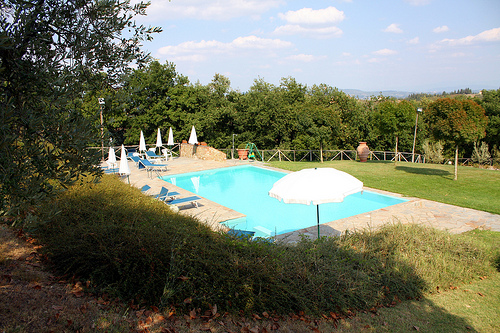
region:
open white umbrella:
[289, 166, 349, 198]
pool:
[190, 161, 255, 203]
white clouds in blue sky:
[176, 0, 210, 32]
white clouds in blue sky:
[175, 29, 227, 69]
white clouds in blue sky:
[240, 19, 317, 57]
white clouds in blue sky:
[246, 21, 330, 88]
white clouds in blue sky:
[306, 6, 361, 38]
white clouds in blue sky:
[309, 38, 359, 69]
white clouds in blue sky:
[363, 25, 428, 63]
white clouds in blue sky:
[363, 46, 421, 87]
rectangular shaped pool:
[164, 149, 401, 232]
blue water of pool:
[160, 161, 395, 242]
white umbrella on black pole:
[274, 164, 366, 242]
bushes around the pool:
[23, 174, 492, 319]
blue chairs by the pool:
[107, 145, 258, 242]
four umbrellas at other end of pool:
[139, 119, 197, 156]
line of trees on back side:
[75, 60, 495, 164]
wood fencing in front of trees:
[93, 137, 480, 168]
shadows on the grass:
[319, 236, 475, 331]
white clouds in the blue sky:
[148, 10, 494, 101]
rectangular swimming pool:
[163, 156, 415, 242]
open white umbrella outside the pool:
[266, 160, 369, 250]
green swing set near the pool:
[238, 141, 263, 166]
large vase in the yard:
[354, 139, 374, 165]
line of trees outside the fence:
[98, 61, 499, 166]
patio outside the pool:
[90, 149, 499, 279]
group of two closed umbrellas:
[105, 138, 130, 188]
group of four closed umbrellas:
[131, 109, 198, 158]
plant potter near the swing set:
[233, 145, 248, 160]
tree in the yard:
[426, 91, 493, 185]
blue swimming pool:
[219, 166, 269, 203]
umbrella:
[277, 162, 345, 212]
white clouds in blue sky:
[177, 6, 237, 44]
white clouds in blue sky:
[219, 5, 291, 55]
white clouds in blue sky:
[353, 28, 403, 68]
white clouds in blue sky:
[390, 15, 445, 49]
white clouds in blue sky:
[385, 32, 443, 83]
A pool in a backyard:
[101, 130, 470, 282]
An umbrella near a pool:
[259, 159, 360, 247]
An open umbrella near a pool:
[267, 163, 369, 237]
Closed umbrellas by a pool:
[123, 123, 205, 161]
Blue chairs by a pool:
[121, 147, 208, 218]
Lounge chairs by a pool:
[130, 141, 209, 225]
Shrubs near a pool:
[48, 170, 418, 307]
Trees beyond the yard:
[116, 42, 494, 157]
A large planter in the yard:
[355, 135, 370, 165]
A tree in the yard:
[417, 95, 478, 181]